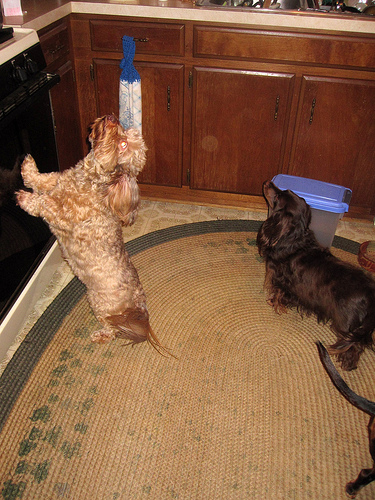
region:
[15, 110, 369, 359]
two dogs are in the kitchen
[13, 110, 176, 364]
the dog has brown fur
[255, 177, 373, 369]
the doggy has black fur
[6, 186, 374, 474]
the kitchen floor has a rug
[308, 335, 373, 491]
the tail and back end of a dog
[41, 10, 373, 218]
the kitchen cabinets are wood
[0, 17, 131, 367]
the dog has her paws on the stove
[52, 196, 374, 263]
the kitchen floor is linoleum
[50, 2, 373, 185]
the hardware on the cabinets is metal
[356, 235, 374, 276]
a dog bowl is on the kitchen floor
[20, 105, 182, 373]
a small light brown dog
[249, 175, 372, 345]
a small dark brown dog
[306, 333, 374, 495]
the back end of a brown dog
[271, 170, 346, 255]
a large plastic container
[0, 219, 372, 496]
a green and tan rug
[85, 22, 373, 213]
some wooden cabinet doors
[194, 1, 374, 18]
a sink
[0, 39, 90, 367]
a white and black oven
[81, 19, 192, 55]
a wooden drawer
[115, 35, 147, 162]
a white and blue plastic bag holder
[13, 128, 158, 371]
dog on hind legs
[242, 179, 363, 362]
dark brown dog looking up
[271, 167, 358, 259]
light blue lid on container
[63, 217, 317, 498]
rug is brown and grey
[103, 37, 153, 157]
blue and white decorative towel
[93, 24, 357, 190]
cabinets are dark brown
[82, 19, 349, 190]
cabinets are red wood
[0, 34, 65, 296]
range is black and white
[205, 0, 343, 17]
stainless steel sink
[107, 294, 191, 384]
dog has dark brown tail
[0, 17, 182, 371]
Tan dog with curly hair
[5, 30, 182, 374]
Tan dog with with front paw on black stove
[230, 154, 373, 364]
Black and brown dog with long hair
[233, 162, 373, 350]
Dog standing on rug in kitchen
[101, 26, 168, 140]
Blue kitchen towel hanging on cabniet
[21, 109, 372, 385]
Dogs standing on kitchen rug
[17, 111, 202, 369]
dog jumping on black stove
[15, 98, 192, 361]
dog jumping on black stove in kitchen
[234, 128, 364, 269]
Blue and clear tupperware container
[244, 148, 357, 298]
Blue and clear tupperware container on kitchen floor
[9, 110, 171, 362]
dog standing on a rug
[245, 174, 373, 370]
dog standing on a rug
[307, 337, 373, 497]
dog standing on a rug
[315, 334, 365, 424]
tail of a dog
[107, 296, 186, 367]
tail of a dog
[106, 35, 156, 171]
towel hanging from a cabinet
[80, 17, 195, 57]
wooden cabinet drawer face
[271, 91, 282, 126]
metal cabinet door handle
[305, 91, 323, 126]
metal cabinet door handle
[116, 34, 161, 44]
metal cabinet door handle